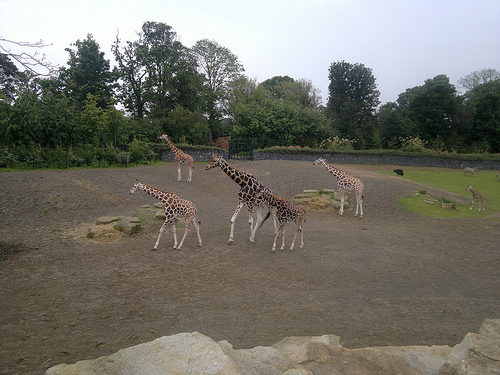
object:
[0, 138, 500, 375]
pen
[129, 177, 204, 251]
giraffe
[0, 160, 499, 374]
dirt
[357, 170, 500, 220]
grass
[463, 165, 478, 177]
zebra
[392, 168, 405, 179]
bird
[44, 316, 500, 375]
wall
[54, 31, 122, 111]
tree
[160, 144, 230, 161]
fence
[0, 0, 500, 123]
sky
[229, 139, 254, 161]
gate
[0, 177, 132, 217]
outcropping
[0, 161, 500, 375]
field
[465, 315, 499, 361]
rock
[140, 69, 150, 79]
branch